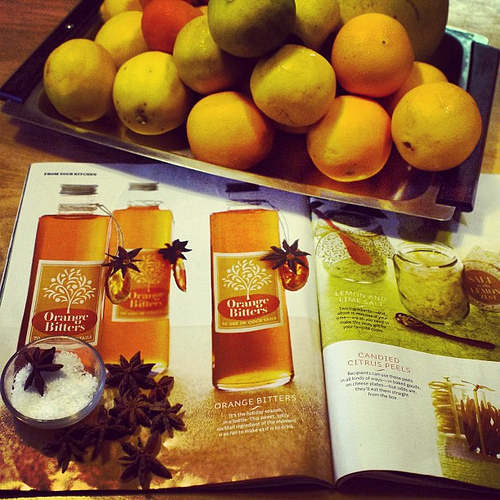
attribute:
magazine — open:
[3, 159, 499, 498]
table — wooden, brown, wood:
[2, 3, 499, 499]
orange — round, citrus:
[329, 12, 415, 100]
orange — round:
[389, 77, 484, 172]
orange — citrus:
[304, 93, 396, 186]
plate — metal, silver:
[4, 2, 499, 225]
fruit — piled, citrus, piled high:
[43, 0, 486, 188]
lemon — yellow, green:
[111, 45, 192, 137]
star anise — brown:
[101, 351, 157, 396]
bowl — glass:
[2, 330, 114, 438]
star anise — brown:
[117, 426, 175, 492]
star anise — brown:
[102, 245, 143, 279]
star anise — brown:
[13, 345, 62, 395]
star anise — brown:
[262, 238, 312, 276]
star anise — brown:
[109, 390, 152, 429]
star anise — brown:
[152, 399, 188, 439]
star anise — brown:
[42, 425, 93, 467]